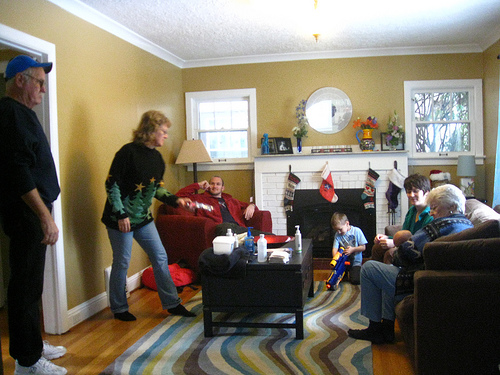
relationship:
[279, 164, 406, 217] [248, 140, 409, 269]
stockings on fireplace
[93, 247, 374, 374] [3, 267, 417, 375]
carpet on floor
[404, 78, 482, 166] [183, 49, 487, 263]
window on wall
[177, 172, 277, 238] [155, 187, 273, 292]
man in chair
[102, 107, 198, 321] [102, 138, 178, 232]
woman in christmas sweater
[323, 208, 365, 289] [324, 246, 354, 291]
boy with toy gun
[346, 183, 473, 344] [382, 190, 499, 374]
woman on couch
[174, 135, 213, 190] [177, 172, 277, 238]
lamp behind man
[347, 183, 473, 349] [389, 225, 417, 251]
woman holding baby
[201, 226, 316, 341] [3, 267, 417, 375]
table on floor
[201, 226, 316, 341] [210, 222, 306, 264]
table with gifts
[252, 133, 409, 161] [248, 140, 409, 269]
mantel on fireplace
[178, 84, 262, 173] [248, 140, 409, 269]
window near fireplace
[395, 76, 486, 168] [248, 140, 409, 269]
window near fireplace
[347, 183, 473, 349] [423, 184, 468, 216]
woman has blonde hair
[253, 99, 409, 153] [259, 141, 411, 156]
knick knacks on mantle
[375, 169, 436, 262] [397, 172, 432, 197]
woman has short hair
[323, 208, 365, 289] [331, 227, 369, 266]
boy in blue shirt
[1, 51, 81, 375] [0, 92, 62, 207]
man in black shirt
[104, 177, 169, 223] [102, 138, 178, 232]
christmas tree on sweater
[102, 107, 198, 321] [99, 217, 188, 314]
woman wearing jeans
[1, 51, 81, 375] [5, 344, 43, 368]
man wearing black socks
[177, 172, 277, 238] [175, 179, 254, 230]
man wearing red jacket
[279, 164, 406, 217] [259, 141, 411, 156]
stockings on mantle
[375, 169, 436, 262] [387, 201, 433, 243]
woman in green shirt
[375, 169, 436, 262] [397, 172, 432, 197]
woman has dark hair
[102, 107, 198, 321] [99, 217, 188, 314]
woman wearing blue pants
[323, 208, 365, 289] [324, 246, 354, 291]
child has gun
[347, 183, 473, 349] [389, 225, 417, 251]
woman holds baby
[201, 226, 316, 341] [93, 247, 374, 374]
table on rug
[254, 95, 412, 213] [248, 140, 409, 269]
items on fireplace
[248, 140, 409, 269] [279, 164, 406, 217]
fireplace has stockings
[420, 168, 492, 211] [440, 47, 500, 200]
stand in corner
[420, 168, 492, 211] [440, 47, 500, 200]
table in corner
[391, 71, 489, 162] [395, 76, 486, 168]
frame on window